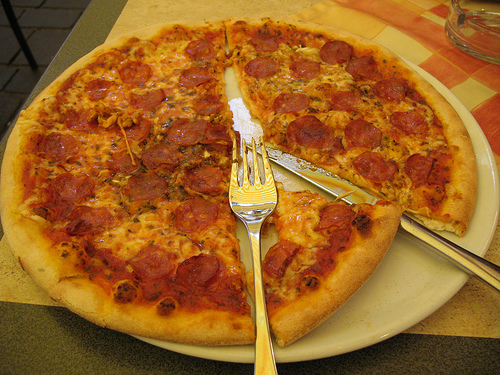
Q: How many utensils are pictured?
A: Two.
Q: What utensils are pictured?
A: A fork and a knife.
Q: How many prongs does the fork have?
A: Four.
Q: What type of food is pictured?
A: A pizza.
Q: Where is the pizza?
A: On a plate.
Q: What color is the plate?
A: White.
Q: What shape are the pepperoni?
A: Round.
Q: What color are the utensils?
A: Silver.